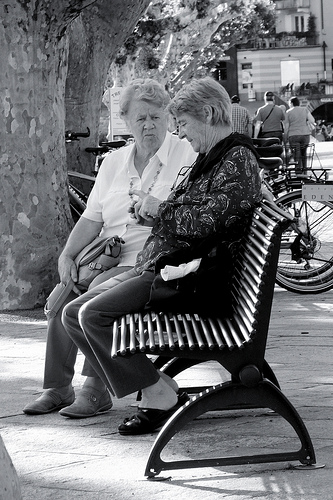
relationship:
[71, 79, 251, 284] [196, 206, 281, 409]
women on bench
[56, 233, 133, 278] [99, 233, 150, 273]
purse on lap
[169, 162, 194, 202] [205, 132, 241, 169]
glasses on neck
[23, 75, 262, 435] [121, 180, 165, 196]
2nd woman in necklace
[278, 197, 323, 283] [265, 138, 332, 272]
wheel on bike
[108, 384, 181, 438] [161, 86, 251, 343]
shoe on 2nd woman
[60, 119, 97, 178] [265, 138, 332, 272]
handlebars of bike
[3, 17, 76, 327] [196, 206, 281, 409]
tree trunk by bench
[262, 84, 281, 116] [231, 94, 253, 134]
hat on people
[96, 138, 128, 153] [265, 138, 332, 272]
seat on bike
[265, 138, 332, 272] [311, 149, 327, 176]
bikes at bike rack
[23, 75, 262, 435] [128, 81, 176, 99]
2nd woman with gray hair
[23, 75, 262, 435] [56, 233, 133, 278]
2nd woman with purse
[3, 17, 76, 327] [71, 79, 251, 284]
tree trunk behind women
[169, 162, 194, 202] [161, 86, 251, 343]
glasses on 2nd woman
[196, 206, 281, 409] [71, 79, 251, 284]
bench with women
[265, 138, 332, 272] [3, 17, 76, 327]
bike by tree trunk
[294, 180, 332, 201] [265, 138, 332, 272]
sign on bike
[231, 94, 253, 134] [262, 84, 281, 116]
people in hat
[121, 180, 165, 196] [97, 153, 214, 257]
necklace on white shirt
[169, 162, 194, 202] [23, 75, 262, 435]
glasses on 2nd woman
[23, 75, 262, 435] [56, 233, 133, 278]
2nd woman holding purse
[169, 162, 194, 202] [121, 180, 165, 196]
glasses on necklace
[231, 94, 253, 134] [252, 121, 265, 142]
people carrying shoulder bag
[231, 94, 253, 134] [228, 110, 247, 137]
people in plaid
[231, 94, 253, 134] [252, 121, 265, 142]
people with shoulder bag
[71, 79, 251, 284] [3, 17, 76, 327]
women under tree trunk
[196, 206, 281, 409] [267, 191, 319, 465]
bench has back